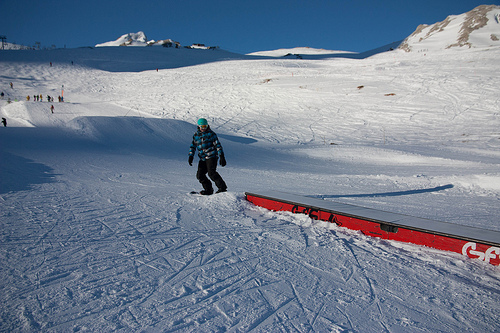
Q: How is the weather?
A: It is clear.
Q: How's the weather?
A: It is clear.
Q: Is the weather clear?
A: Yes, it is clear.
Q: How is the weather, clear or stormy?
A: It is clear.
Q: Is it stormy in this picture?
A: No, it is clear.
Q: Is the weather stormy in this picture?
A: No, it is clear.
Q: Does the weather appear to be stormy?
A: No, it is clear.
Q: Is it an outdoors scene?
A: Yes, it is outdoors.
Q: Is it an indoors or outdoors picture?
A: It is outdoors.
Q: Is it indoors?
A: No, it is outdoors.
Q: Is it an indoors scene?
A: No, it is outdoors.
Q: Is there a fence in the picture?
A: No, there are no fences.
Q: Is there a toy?
A: No, there are no toys.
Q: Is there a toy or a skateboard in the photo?
A: No, there are no toys or skateboards.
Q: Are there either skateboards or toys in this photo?
A: No, there are no toys or skateboards.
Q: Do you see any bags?
A: No, there are no bags.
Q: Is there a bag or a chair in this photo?
A: No, there are no bags or chairs.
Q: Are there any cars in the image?
A: No, there are no cars.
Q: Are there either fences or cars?
A: No, there are no cars or fences.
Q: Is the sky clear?
A: Yes, the sky is clear.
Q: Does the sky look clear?
A: Yes, the sky is clear.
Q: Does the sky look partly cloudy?
A: No, the sky is clear.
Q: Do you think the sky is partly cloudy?
A: No, the sky is clear.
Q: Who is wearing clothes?
A: The man is wearing clothes.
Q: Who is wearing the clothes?
A: The man is wearing clothes.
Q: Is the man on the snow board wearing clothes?
A: Yes, the man is wearing clothes.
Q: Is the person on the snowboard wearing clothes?
A: Yes, the man is wearing clothes.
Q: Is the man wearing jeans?
A: No, the man is wearing clothes.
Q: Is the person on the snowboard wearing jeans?
A: No, the man is wearing clothes.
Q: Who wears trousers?
A: The man wears trousers.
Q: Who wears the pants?
A: The man wears trousers.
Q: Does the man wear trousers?
A: Yes, the man wears trousers.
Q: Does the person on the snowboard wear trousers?
A: Yes, the man wears trousers.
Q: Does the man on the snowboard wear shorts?
A: No, the man wears trousers.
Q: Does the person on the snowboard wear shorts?
A: No, the man wears trousers.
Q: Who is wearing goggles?
A: The man is wearing goggles.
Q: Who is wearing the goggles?
A: The man is wearing goggles.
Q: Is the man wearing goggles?
A: Yes, the man is wearing goggles.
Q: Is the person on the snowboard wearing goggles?
A: Yes, the man is wearing goggles.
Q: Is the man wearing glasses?
A: No, the man is wearing goggles.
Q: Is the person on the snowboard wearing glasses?
A: No, the man is wearing goggles.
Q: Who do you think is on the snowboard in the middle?
A: The man is on the snowboard.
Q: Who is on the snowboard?
A: The man is on the snowboard.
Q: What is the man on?
A: The man is on the snowboard.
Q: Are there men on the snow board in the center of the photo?
A: Yes, there is a man on the snowboard.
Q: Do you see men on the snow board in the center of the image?
A: Yes, there is a man on the snowboard.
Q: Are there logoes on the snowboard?
A: No, there is a man on the snowboard.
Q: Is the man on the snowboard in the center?
A: Yes, the man is on the snowboard.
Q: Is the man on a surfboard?
A: No, the man is on the snowboard.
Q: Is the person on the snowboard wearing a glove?
A: Yes, the man is wearing a glove.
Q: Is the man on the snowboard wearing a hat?
A: No, the man is wearing a glove.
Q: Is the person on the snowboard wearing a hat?
A: No, the man is wearing a glove.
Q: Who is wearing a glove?
A: The man is wearing a glove.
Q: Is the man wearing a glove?
A: Yes, the man is wearing a glove.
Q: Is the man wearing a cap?
A: No, the man is wearing a glove.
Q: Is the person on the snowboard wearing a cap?
A: No, the man is wearing a glove.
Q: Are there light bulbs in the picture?
A: No, there are no light bulbs.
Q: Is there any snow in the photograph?
A: Yes, there is snow.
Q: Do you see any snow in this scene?
A: Yes, there is snow.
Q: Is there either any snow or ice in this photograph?
A: Yes, there is snow.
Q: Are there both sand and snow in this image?
A: No, there is snow but no sand.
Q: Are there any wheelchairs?
A: No, there are no wheelchairs.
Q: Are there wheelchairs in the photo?
A: No, there are no wheelchairs.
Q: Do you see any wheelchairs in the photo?
A: No, there are no wheelchairs.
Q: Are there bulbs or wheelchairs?
A: No, there are no wheelchairs or bulbs.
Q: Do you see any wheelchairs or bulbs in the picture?
A: No, there are no wheelchairs or bulbs.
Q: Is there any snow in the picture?
A: Yes, there is snow.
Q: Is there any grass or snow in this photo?
A: Yes, there is snow.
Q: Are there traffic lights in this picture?
A: No, there are no traffic lights.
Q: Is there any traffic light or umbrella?
A: No, there are no traffic lights or umbrellas.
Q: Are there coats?
A: Yes, there is a coat.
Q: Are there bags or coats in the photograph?
A: Yes, there is a coat.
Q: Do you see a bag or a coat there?
A: Yes, there is a coat.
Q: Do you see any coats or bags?
A: Yes, there is a coat.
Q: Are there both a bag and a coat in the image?
A: No, there is a coat but no bags.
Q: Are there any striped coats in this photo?
A: Yes, there is a striped coat.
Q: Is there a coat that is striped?
A: Yes, there is a coat that is striped.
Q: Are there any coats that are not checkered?
A: Yes, there is a striped coat.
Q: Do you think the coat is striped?
A: Yes, the coat is striped.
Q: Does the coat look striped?
A: Yes, the coat is striped.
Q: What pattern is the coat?
A: The coat is striped.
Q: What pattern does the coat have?
A: The coat has striped pattern.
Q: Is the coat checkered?
A: No, the coat is striped.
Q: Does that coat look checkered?
A: No, the coat is striped.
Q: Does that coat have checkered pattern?
A: No, the coat is striped.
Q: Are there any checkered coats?
A: No, there is a coat but it is striped.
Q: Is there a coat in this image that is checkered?
A: No, there is a coat but it is striped.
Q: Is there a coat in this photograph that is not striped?
A: No, there is a coat but it is striped.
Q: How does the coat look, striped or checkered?
A: The coat is striped.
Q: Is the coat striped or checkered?
A: The coat is striped.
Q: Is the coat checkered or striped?
A: The coat is striped.